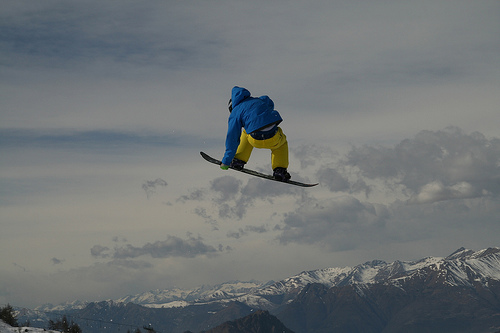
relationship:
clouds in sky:
[8, 3, 498, 263] [0, 2, 498, 302]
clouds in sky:
[50, 257, 63, 264] [7, 123, 195, 245]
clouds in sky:
[50, 257, 63, 264] [0, 2, 498, 302]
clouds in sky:
[50, 257, 63, 264] [0, 4, 492, 244]